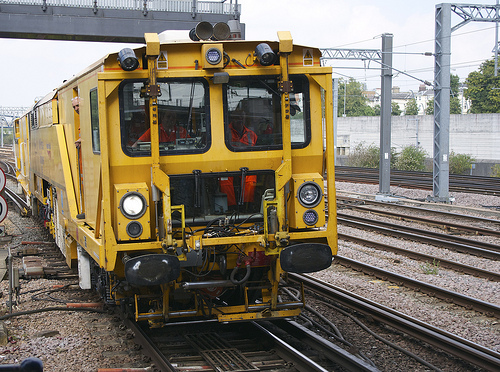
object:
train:
[7, 14, 349, 336]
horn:
[191, 19, 218, 41]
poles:
[370, 21, 400, 202]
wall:
[344, 116, 499, 166]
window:
[219, 82, 313, 154]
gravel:
[320, 234, 497, 313]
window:
[87, 85, 104, 156]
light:
[295, 180, 323, 205]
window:
[159, 167, 279, 234]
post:
[428, 2, 453, 200]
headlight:
[118, 49, 141, 70]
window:
[115, 79, 213, 156]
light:
[120, 189, 145, 217]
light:
[299, 181, 319, 209]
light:
[197, 41, 230, 74]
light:
[250, 45, 277, 67]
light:
[113, 45, 145, 67]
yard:
[331, 136, 493, 183]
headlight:
[301, 182, 319, 207]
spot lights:
[118, 45, 141, 67]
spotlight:
[254, 38, 279, 68]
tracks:
[373, 197, 470, 344]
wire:
[0, 254, 109, 336]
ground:
[0, 183, 500, 370]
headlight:
[115, 190, 147, 225]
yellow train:
[13, 30, 353, 350]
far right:
[389, 75, 483, 186]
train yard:
[16, 10, 476, 362]